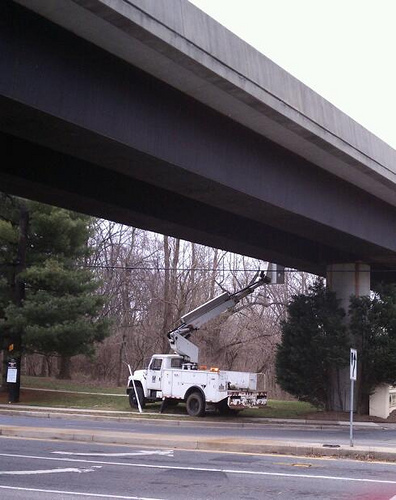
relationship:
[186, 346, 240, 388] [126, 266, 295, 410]
lights on truck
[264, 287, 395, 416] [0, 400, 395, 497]
bush next to road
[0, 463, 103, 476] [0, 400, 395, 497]
arrow on road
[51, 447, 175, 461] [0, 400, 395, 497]
arrow on road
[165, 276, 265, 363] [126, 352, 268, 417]
lift on truck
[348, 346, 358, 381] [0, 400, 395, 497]
sign on road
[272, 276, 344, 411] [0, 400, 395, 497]
tree around road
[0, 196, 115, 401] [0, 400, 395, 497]
tree around road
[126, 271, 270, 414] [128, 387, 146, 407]
truck has front tire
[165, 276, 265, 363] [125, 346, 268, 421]
lift for truck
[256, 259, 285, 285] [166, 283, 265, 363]
cage atop lift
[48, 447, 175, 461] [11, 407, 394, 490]
arrow on ground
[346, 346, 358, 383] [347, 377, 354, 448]
sign on post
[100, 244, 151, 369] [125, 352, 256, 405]
trees behind truck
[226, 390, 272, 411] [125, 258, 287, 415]
rust on back of truck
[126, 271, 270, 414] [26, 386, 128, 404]
truck parked on grass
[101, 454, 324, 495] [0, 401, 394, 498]
line on street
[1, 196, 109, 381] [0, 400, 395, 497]
tree next to road